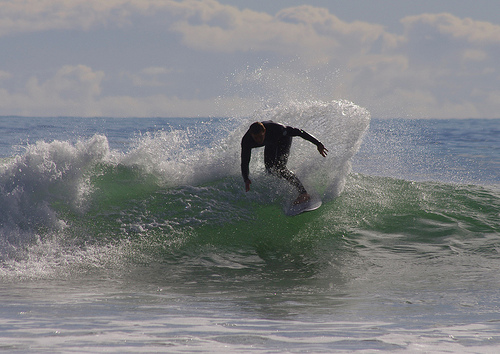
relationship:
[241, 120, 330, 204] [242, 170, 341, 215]
man on surfboard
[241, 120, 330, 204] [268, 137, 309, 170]
man in wetsuit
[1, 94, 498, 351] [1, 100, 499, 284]
water behind wave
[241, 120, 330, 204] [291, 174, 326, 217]
man on surfboard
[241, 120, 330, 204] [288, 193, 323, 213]
man riding a surfboard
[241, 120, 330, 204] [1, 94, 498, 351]
man on water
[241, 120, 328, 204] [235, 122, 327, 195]
man wearing wetsuit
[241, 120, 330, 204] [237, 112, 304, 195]
man wearing wetsuit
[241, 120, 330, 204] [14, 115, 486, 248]
man surfing a wave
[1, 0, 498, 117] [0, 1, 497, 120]
clouds in sky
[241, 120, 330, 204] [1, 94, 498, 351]
man leaning over water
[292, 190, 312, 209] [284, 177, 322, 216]
foot on surfboard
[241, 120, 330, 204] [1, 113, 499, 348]
man in sea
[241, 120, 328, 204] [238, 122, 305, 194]
man wears a wetsuit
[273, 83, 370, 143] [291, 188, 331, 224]
splash above surfboard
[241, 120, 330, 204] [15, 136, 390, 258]
man catching wave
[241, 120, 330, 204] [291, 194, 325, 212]
man on surfboard